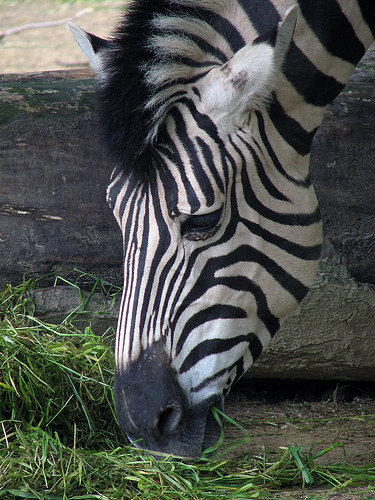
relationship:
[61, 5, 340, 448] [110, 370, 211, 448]
zebra has a nose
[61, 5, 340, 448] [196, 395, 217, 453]
zebra has mouth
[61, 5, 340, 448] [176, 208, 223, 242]
zebra has a eye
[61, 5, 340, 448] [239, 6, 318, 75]
zebra has an ear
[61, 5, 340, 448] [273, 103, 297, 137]
zebra has a stripe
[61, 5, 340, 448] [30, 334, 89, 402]
zebra eating grass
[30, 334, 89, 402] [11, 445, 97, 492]
grass on ground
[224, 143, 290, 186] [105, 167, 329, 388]
strips on face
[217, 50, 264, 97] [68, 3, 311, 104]
hair on ears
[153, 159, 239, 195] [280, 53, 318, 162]
stripes on neck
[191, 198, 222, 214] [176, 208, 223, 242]
hair near eye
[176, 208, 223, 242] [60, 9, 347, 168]
eye on head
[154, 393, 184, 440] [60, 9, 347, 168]
nostril on head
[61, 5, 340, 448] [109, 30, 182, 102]
zebra has a mane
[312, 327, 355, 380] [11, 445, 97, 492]
dirt on ground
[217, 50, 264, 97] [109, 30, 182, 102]
hair on mane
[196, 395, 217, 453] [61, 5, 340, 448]
mouth on zebra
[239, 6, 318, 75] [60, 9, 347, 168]
ear on head